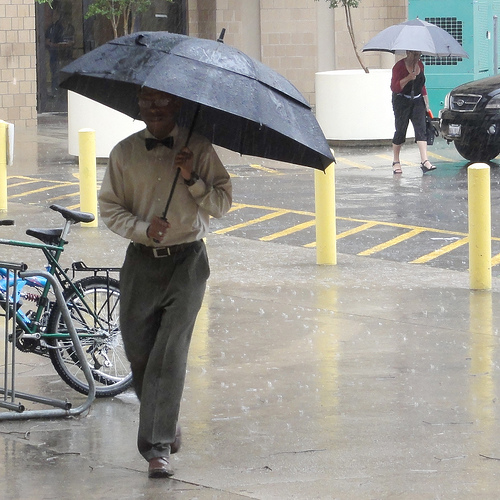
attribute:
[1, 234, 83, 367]
bikes — secured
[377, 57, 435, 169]
woman — walking, light skinned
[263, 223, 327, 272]
street — wet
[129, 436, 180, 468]
shoes — brown, leather, black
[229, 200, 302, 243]
lines — painted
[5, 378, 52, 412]
rack — metal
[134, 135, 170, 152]
bow tie — black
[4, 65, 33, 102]
building — brick, tan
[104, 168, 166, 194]
shirt — brown, green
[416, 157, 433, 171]
sandals — black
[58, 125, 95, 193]
pole — yellow, cement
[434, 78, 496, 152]
vehicle — black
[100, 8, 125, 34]
tree — small, planted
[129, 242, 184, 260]
belt — black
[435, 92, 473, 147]
suv — black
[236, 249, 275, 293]
floor — wet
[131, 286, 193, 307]
trousers — black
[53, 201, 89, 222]
seat — raised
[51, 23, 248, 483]
man — walking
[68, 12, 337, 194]
umbrella — black, big, multicolored